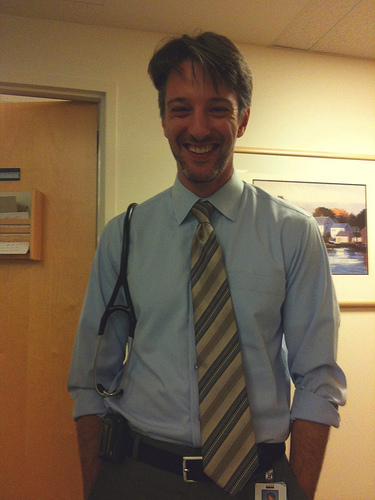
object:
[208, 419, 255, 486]
stripe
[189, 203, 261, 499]
tie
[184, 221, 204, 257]
stripe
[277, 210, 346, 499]
arm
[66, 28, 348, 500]
man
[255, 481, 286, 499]
card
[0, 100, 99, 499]
door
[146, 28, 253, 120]
hair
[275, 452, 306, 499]
pocket